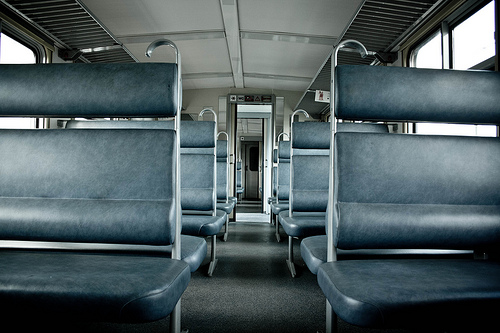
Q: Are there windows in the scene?
A: Yes, there is a window.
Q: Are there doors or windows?
A: Yes, there is a window.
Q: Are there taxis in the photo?
A: No, there are no taxis.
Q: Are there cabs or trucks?
A: No, there are no cabs or trucks.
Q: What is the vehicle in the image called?
A: The vehicle is a train car.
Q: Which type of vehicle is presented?
A: The vehicle is a train car.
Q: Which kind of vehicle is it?
A: The vehicle is a train car.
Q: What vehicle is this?
A: This is a train car.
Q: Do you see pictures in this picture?
A: No, there are no pictures.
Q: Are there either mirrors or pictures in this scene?
A: No, there are no pictures or mirrors.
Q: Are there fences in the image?
A: No, there are no fences.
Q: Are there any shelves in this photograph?
A: No, there are no shelves.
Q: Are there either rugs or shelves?
A: No, there are no shelves or rugs.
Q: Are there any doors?
A: Yes, there is a door.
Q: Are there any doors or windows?
A: Yes, there is a door.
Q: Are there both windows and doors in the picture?
A: Yes, there are both a door and windows.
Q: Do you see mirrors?
A: No, there are no mirrors.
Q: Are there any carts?
A: No, there are no carts.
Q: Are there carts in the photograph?
A: No, there are no carts.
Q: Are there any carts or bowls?
A: No, there are no carts or bowls.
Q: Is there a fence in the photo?
A: No, there are no fences.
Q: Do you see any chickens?
A: No, there are no chickens.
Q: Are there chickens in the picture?
A: No, there are no chickens.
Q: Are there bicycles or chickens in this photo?
A: No, there are no chickens or bicycles.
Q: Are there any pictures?
A: No, there are no pictures.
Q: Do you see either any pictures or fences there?
A: No, there are no pictures or fences.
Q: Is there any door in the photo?
A: Yes, there is a door.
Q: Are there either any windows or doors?
A: Yes, there is a door.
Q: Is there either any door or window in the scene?
A: Yes, there is a door.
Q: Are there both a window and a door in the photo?
A: Yes, there are both a door and a window.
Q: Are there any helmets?
A: No, there are no helmets.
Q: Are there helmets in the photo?
A: No, there are no helmets.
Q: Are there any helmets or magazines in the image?
A: No, there are no helmets or magazines.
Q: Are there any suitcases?
A: No, there are no suitcases.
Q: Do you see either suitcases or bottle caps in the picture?
A: No, there are no suitcases or bottle caps.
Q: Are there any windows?
A: Yes, there is a window.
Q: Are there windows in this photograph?
A: Yes, there is a window.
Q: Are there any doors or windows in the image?
A: Yes, there is a window.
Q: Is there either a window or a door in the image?
A: Yes, there is a window.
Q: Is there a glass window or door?
A: Yes, there is a glass window.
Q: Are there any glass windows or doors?
A: Yes, there is a glass window.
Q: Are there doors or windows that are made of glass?
A: Yes, the window is made of glass.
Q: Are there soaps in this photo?
A: No, there are no soaps.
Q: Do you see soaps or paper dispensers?
A: No, there are no soaps or paper dispensers.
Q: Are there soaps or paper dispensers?
A: No, there are no soaps or paper dispensers.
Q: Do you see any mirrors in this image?
A: No, there are no mirrors.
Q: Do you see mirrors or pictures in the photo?
A: No, there are no mirrors or pictures.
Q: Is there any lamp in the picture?
A: No, there are no lamps.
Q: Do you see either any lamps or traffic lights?
A: No, there are no lamps or traffic lights.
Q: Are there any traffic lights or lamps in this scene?
A: No, there are no lamps or traffic lights.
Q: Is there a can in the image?
A: No, there are no cans.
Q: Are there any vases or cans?
A: No, there are no cans or vases.